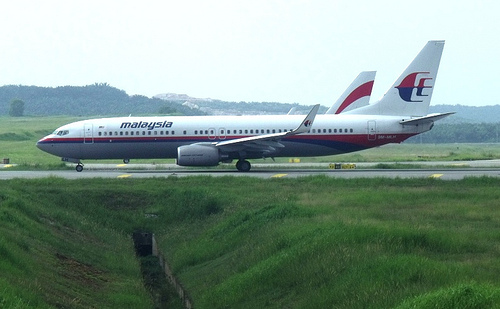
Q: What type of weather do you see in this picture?
A: It is cloudy.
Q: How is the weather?
A: It is cloudy.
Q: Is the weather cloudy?
A: Yes, it is cloudy.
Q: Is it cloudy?
A: Yes, it is cloudy.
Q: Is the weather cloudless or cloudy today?
A: It is cloudy.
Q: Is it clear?
A: No, it is cloudy.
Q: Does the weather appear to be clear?
A: No, it is cloudy.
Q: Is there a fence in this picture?
A: No, there are no fences.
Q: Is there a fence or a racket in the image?
A: No, there are no fences or rackets.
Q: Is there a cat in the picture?
A: No, there are no cats.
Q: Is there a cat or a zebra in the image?
A: No, there are no cats or zebras.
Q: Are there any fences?
A: No, there are no fences.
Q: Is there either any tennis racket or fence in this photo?
A: No, there are no fences or rackets.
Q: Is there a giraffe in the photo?
A: No, there are no giraffes.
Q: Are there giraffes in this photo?
A: No, there are no giraffes.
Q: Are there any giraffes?
A: No, there are no giraffes.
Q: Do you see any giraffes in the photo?
A: No, there are no giraffes.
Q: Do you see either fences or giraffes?
A: No, there are no giraffes or fences.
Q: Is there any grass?
A: Yes, there is grass.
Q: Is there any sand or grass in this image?
A: Yes, there is grass.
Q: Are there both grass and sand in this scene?
A: No, there is grass but no sand.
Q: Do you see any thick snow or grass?
A: Yes, there is thick grass.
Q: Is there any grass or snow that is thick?
A: Yes, the grass is thick.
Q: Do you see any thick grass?
A: Yes, there is thick grass.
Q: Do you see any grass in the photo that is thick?
A: Yes, there is grass that is thick.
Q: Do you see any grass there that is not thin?
A: Yes, there is thick grass.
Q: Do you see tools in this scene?
A: No, there are no tools.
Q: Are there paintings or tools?
A: No, there are no tools or paintings.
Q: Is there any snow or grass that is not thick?
A: No, there is grass but it is thick.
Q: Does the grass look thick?
A: Yes, the grass is thick.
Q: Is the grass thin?
A: No, the grass is thick.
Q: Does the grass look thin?
A: No, the grass is thick.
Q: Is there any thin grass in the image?
A: No, there is grass but it is thick.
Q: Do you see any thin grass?
A: No, there is grass but it is thick.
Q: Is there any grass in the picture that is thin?
A: No, there is grass but it is thick.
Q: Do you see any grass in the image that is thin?
A: No, there is grass but it is thick.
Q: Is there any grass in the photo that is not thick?
A: No, there is grass but it is thick.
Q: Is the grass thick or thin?
A: The grass is thick.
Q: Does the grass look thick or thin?
A: The grass is thick.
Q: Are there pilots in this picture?
A: No, there are no pilots.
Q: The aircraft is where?
A: The aircraft is on the runway.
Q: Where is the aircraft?
A: The aircraft is on the runway.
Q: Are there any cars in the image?
A: No, there are no cars.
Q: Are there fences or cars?
A: No, there are no cars or fences.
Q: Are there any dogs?
A: No, there are no dogs.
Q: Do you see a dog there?
A: No, there are no dogs.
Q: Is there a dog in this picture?
A: No, there are no dogs.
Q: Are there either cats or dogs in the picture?
A: No, there are no dogs or cats.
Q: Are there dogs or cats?
A: No, there are no dogs or cats.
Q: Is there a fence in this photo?
A: No, there are no fences.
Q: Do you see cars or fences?
A: No, there are no fences or cars.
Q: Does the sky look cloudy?
A: Yes, the sky is cloudy.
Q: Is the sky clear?
A: No, the sky is cloudy.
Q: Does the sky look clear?
A: No, the sky is cloudy.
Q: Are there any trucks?
A: No, there are no trucks.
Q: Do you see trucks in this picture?
A: No, there are no trucks.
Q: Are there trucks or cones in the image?
A: No, there are no trucks or cones.